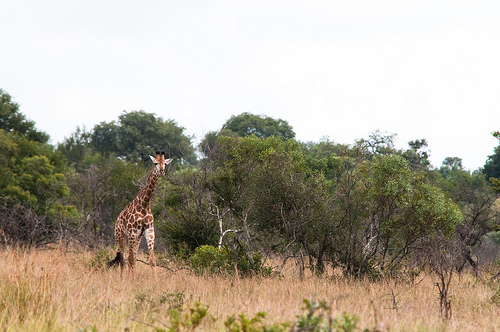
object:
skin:
[123, 212, 137, 224]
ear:
[147, 154, 156, 161]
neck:
[125, 167, 161, 207]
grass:
[9, 261, 84, 312]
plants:
[265, 286, 360, 331]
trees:
[234, 140, 352, 276]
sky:
[1, 0, 499, 175]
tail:
[105, 240, 121, 266]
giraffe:
[104, 150, 176, 282]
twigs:
[371, 266, 403, 311]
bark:
[218, 236, 224, 249]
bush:
[175, 244, 279, 275]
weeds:
[84, 294, 122, 315]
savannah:
[2, 237, 497, 332]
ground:
[403, 290, 500, 331]